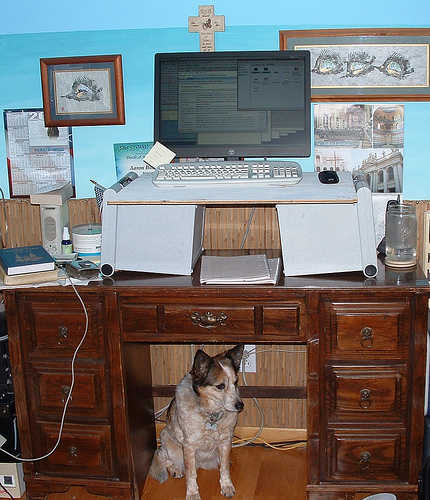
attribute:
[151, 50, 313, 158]
monitor — on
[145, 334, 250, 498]
dog — light, dark, sitting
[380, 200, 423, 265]
jar — glass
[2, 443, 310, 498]
floor — wooden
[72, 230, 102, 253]
discs — spindled, black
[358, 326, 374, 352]
handle — three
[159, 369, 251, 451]
dog — sitting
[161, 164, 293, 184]
keyboard — gray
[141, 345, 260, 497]
dog — brown 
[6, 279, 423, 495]
table — wooden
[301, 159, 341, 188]
phone — black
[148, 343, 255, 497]
dog — brown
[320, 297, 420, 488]
drawers — three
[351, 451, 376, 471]
handle — circular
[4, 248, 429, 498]
desk — wooden, old